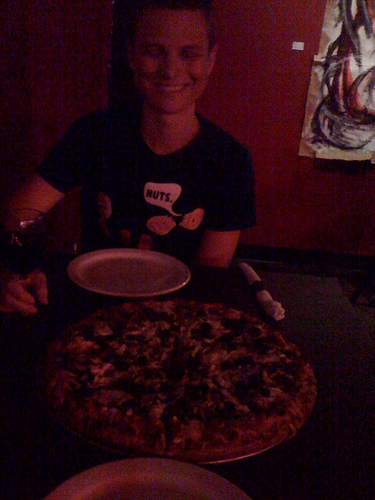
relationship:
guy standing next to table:
[0, 0, 258, 315] [0, 267, 371, 496]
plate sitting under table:
[64, 227, 231, 318] [299, 284, 337, 339]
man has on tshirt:
[88, 38, 269, 238] [37, 101, 268, 255]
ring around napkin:
[237, 266, 284, 298] [195, 248, 320, 352]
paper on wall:
[295, 0, 373, 158] [0, 1, 373, 256]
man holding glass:
[0, 0, 240, 313] [2, 203, 52, 279]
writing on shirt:
[142, 180, 176, 206] [25, 113, 262, 271]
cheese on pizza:
[48, 300, 313, 452] [40, 284, 329, 464]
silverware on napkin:
[251, 280, 265, 301] [224, 259, 296, 348]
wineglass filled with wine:
[6, 204, 47, 278] [13, 204, 55, 271]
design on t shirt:
[141, 178, 186, 218] [32, 98, 261, 294]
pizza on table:
[40, 302, 316, 457] [19, 251, 355, 470]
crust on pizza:
[199, 384, 297, 456] [40, 284, 329, 464]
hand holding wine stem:
[6, 259, 57, 304] [18, 280, 36, 319]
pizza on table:
[40, 284, 329, 464] [0, 267, 371, 496]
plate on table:
[67, 247, 190, 296] [58, 245, 356, 458]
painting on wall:
[295, 3, 374, 173] [0, 1, 373, 256]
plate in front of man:
[67, 247, 190, 296] [0, 0, 240, 313]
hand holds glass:
[0, 269, 48, 315] [4, 203, 46, 305]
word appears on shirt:
[143, 187, 170, 202] [36, 104, 257, 268]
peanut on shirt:
[147, 203, 208, 237] [36, 104, 257, 268]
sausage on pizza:
[195, 323, 216, 340] [234, 350, 299, 421]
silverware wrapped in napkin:
[242, 264, 287, 325] [242, 273, 293, 322]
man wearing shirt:
[0, 0, 240, 313] [25, 113, 262, 271]